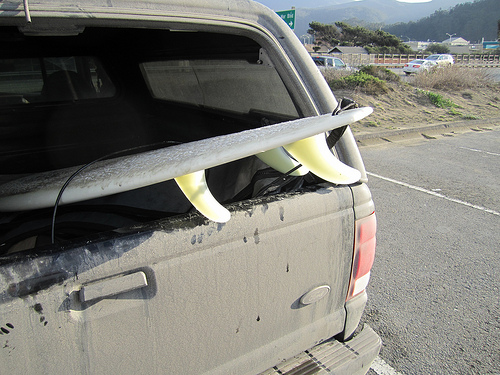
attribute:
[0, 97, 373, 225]
surfboard — white, grey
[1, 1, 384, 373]
suv — dirty, parked in stall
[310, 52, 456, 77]
cars — traveling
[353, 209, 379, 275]
brake lights — red, white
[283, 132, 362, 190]
fin — yellow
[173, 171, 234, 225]
fin — yellow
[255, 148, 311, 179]
fin — yellow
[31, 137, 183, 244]
cord — black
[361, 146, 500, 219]
lines — white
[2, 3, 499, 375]
parking lot — paved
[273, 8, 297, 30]
street sign — green, white, showing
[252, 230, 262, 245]
spots — clean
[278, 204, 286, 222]
spots — clean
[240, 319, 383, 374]
back bumper — dusty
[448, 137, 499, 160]
stripe — white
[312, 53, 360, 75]
car — driving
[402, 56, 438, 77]
car — driving, white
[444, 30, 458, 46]
light pole — double headed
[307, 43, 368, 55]
house — white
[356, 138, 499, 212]
parking space — empty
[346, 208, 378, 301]
tail light — red, white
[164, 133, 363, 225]
fins — yellow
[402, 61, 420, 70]
tail lights — red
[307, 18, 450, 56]
evergreen shrub — wide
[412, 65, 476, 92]
grass shrub — tan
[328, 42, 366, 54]
roof — dark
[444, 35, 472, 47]
house — white